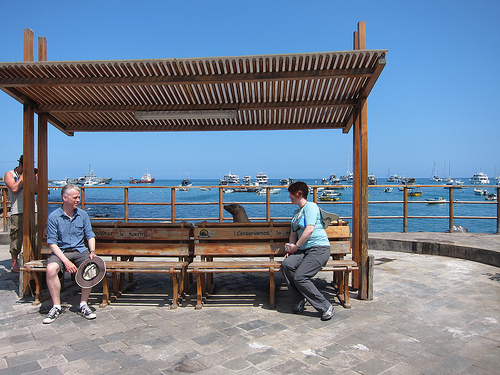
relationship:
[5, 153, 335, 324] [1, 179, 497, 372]
strangers in harbor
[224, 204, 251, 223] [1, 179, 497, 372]
sea lion in harbor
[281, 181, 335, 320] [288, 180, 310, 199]
person has hair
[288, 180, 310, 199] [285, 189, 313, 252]
hair has skin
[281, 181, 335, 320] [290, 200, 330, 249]
person wearing a shirt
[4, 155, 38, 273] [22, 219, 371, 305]
man sitting on a bench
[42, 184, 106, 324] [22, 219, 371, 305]
man sitting on a bench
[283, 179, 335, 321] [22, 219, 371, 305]
person sitting on a bench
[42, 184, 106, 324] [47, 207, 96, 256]
man wearing blue shirt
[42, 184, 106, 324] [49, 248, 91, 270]
man wearing shorts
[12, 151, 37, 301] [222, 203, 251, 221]
man photographing an animal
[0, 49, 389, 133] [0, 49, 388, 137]
slats on awning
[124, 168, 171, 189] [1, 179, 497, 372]
boat in harbor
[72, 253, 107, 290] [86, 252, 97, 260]
hat in hand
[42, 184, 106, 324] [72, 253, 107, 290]
man holding hat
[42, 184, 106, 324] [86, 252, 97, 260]
man has a hand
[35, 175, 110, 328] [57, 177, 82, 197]
man has hair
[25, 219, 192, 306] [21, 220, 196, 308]
rust on a bench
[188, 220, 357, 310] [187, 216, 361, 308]
rust on a bench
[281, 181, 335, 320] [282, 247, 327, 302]
person has pants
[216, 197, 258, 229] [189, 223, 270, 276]
sea lion sitting on bench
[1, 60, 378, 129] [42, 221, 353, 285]
awning above benches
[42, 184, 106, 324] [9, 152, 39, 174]
man wearing hat